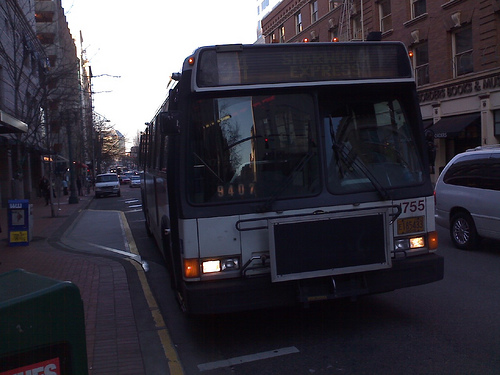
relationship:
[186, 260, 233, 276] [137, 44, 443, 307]
light on bus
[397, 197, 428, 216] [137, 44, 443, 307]
number on bus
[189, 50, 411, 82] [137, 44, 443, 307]
sign on bus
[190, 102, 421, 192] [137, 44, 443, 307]
window on bus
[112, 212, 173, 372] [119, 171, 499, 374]
curb on street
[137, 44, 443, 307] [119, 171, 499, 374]
bus on street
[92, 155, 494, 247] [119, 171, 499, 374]
cars on street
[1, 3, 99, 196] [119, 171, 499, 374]
building next to road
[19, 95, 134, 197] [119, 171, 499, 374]
trees next to road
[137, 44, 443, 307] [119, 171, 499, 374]
bus on road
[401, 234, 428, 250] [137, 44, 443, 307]
headlight on bus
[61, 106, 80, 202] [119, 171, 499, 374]
pole on street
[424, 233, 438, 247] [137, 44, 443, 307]
signal on bus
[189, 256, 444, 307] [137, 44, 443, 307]
bumper on bus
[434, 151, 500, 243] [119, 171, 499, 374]
van on street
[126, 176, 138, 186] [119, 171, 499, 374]
car on street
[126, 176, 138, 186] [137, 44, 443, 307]
car next to bus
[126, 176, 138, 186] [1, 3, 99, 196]
car in front of building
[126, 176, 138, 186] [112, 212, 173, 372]
car on curb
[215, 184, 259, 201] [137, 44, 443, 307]
number plate on bus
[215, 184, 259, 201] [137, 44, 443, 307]
numbers on bus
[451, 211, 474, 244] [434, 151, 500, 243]
tire on car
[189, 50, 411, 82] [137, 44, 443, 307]
marquee display on bus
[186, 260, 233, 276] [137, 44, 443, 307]
headlight on bus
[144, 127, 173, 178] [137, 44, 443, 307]
window on bus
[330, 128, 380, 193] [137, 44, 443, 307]
windshield wiper on bus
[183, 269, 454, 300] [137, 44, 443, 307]
fender on bus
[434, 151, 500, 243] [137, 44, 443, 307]
mini van next to bus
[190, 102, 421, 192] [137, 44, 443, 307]
windshield on bus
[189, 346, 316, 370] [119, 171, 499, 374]
white stripe on street